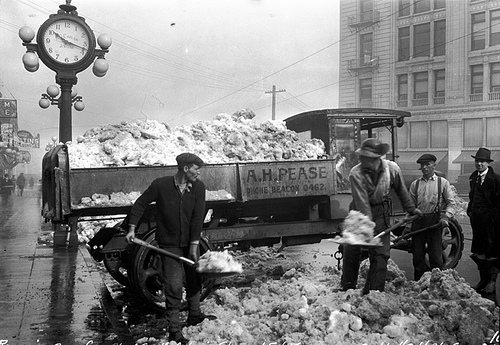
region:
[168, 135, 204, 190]
head of a person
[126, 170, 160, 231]
arm of a person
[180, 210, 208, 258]
arm of a person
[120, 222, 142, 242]
hand of a person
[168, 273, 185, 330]
leg of a person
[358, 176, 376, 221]
arm of a person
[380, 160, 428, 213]
arm of a person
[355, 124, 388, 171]
head of a person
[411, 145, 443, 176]
head of a person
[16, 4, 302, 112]
wires on telephone pole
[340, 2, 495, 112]
windows on city building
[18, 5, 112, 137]
clock with lights on pole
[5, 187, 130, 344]
wet surface of sidewalk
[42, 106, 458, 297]
truck filled with snow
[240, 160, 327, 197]
words on side of truck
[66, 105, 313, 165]
pile of dirty snow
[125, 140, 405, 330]
men with shovels of snow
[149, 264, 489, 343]
pile of snow on street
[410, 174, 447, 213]
suspenders on man's shirt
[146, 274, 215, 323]
legs of the man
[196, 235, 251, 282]
snow on the shovel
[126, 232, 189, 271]
shovel in man's hand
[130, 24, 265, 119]
wires above the land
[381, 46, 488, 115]
windows on the building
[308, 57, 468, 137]
building in the distance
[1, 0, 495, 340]
a vintage photo of an outdoor scene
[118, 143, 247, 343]
I think this guy is shoveling snow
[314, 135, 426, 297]
this man has a shovelful of snow too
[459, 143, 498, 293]
a nattily dressed man observes the shoveling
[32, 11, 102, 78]
the clock reads 10:18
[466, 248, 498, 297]
the observer is wearing galoshes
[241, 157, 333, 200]
the owner of the truck is A.H. Pease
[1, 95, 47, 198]
shop signs in the distance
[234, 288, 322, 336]
the snow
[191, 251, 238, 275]
snow on the shuffle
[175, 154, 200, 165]
man is wearing a hat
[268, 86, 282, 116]
a cross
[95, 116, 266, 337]
A man with a shovel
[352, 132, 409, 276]
A man with a hat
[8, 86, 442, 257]
A very old truck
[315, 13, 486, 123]
A building with lots of windows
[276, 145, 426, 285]
A man with a shovel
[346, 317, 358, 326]
A rock on the ground.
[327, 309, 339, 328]
A rock on the ground.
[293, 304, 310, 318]
A rock on the ground.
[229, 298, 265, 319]
A rock on the ground.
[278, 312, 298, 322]
A rock on the ground.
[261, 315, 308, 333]
A rock on the ground.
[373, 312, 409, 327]
A rock on the ground.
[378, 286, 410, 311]
A rock on the ground.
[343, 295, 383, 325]
A rock on the ground.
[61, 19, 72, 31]
black print style number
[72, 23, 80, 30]
black print style number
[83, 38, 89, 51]
black print style number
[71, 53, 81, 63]
black print style number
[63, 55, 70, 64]
black print style number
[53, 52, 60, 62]
black print style number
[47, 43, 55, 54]
black print style number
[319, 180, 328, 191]
black print style number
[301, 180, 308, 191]
black print style number